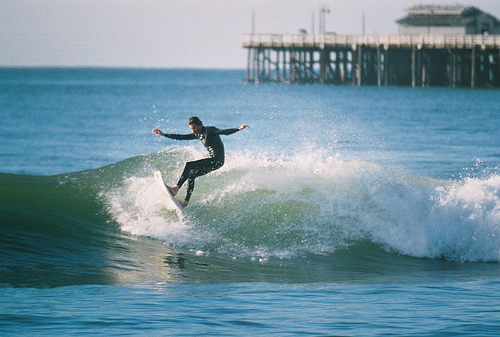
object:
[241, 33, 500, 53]
fence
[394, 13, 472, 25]
roof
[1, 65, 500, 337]
water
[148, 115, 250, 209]
surfer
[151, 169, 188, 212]
board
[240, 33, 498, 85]
deck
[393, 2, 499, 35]
building